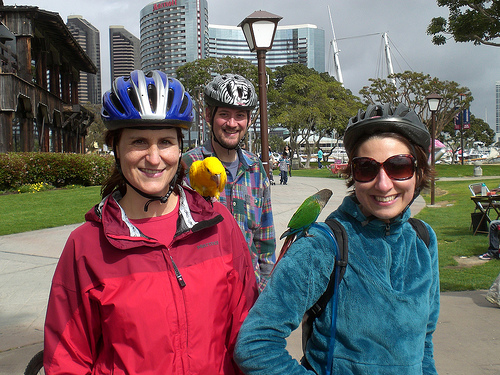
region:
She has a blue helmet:
[95, 63, 195, 129]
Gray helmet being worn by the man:
[200, 73, 259, 108]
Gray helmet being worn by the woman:
[338, 95, 437, 137]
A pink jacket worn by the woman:
[38, 200, 230, 373]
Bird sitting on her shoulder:
[188, 158, 228, 196]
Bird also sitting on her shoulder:
[284, 178, 336, 241]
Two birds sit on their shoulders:
[187, 158, 335, 240]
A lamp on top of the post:
[234, 0, 281, 53]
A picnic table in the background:
[468, 179, 498, 236]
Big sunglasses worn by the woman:
[347, 154, 421, 184]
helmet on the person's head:
[336, 103, 438, 146]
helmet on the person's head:
[100, 67, 203, 137]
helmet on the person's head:
[201, 68, 263, 113]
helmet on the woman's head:
[338, 95, 443, 138]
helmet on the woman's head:
[91, 70, 199, 130]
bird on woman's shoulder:
[188, 156, 229, 203]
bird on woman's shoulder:
[282, 183, 349, 243]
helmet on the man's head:
[207, 70, 258, 107]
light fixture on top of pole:
[234, 10, 283, 50]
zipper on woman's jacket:
[160, 248, 190, 290]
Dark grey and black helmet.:
[342, 100, 429, 150]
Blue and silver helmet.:
[97, 66, 191, 126]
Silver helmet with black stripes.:
[206, 75, 257, 104]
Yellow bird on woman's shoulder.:
[189, 158, 231, 210]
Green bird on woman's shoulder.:
[260, 187, 335, 275]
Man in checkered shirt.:
[181, 70, 291, 280]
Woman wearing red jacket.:
[42, 64, 261, 374]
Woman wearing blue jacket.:
[235, 101, 440, 373]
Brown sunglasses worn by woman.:
[347, 155, 419, 182]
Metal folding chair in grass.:
[465, 180, 499, 230]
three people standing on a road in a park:
[45, 71, 439, 373]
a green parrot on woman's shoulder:
[268, 188, 334, 276]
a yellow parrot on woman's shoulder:
[189, 154, 226, 201]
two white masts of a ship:
[329, 31, 397, 98]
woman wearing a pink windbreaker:
[46, 189, 257, 371]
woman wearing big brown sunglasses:
[348, 154, 420, 182]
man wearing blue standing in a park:
[315, 144, 325, 169]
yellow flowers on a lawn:
[15, 180, 85, 195]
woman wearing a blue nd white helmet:
[100, 73, 192, 129]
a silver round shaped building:
[138, 3, 323, 150]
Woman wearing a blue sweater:
[237, 108, 442, 372]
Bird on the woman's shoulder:
[270, 187, 337, 259]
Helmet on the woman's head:
[332, 99, 434, 149]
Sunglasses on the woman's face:
[344, 154, 424, 188]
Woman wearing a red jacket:
[45, 73, 262, 371]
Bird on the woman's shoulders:
[185, 150, 241, 215]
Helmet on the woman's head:
[95, 65, 201, 131]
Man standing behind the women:
[183, 71, 279, 282]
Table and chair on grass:
[464, 181, 499, 237]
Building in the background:
[127, 16, 332, 130]